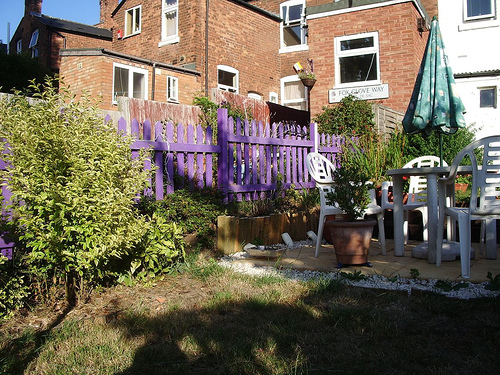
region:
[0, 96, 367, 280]
THIS IS A PICKET FENCE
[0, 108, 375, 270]
THE FENCE IS PURPLE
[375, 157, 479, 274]
THIS IS A TABLE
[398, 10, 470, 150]
THIS IS AN UMBRELLA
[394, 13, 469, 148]
THE UMBRELLA IS BLUE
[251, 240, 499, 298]
THIS IS A CONCRETE SLAB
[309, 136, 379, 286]
THIS IS A PLANT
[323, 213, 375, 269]
THIS IS A POT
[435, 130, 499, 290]
THIS IS A CHAIR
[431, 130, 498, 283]
THE CHAIR IS WHITE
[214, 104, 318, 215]
a stretch of purple fence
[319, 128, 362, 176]
a stretch of purple fence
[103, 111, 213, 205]
a stretch of purple fence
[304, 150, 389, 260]
a white plastic patio chair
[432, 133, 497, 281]
a white plastic patio chair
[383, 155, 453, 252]
a white plastic patio chair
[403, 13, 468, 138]
a closed blue patio umbrella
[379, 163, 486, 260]
a white patio table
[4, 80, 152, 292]
a small green bush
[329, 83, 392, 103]
a white sign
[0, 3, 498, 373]
Outside of a family home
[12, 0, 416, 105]
Large building made of red bricks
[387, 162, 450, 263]
white patio table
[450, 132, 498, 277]
This is one of three chairs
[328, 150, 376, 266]
plant growing in a red clay pot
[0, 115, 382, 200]
purple fence lined behind green tree and white chair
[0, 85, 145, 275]
bright green tree bush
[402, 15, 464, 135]
green umbrella in middle of patio table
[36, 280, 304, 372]
Sunlight shows patches of brown on green grass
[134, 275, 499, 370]
Shadow cover remaining grass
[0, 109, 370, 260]
A purple wooden picket fence.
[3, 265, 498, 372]
A grass with some dead spots.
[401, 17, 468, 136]
A green umbrella closed.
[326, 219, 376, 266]
A brown flower pot.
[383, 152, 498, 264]
A white round table for outdoors.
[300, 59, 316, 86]
A basket hanger on the side of a bricked building.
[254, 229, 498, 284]
Cement blocks underneath the table.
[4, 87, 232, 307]
Bushes and shrubs.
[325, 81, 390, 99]
A sign on a building.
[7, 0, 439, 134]
A large red bricked building.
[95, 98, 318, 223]
wooden fence painted purple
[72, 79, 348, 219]
purple fence in backyard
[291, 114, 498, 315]
white plastic patio furniture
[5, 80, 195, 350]
small tree growing in yard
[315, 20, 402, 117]
fox glove way sign beneath window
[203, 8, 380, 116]
windows with white painted frames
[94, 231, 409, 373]
shadows of trees on ground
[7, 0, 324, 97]
brick building with white window frames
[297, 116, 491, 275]
white patio table with three chairs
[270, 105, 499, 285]
patio furniture on deck in back yard